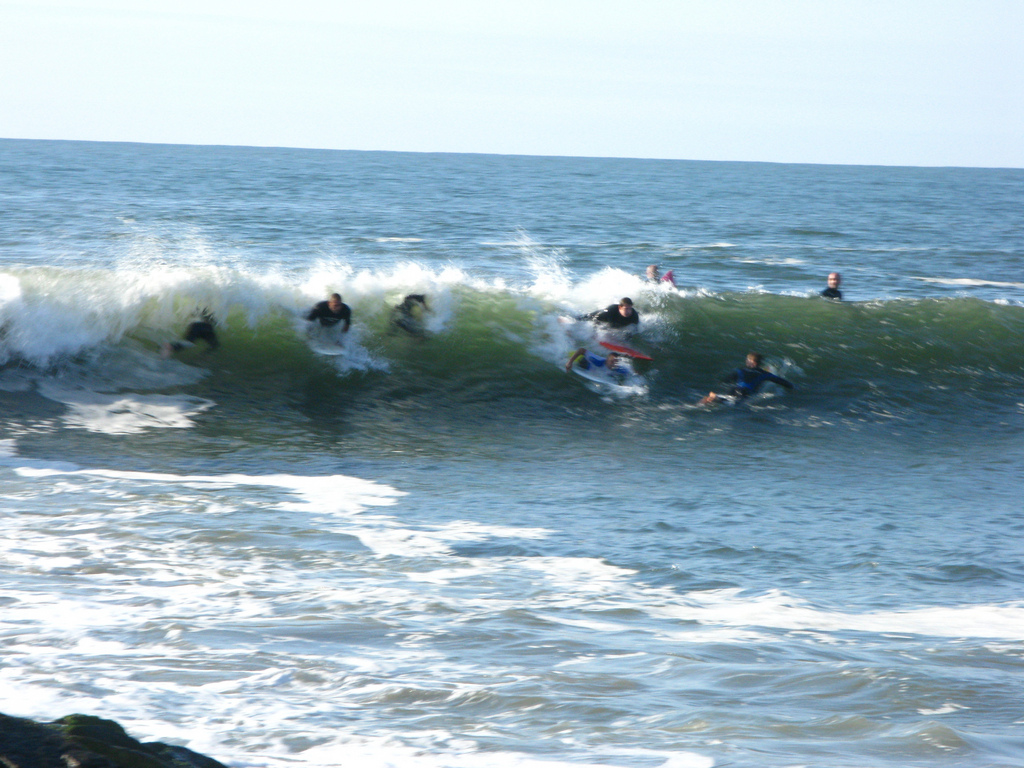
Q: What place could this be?
A: It is an ocean.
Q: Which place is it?
A: It is an ocean.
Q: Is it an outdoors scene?
A: Yes, it is outdoors.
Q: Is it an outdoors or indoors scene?
A: It is outdoors.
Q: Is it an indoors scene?
A: No, it is outdoors.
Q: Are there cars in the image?
A: No, there are no cars.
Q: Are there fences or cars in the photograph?
A: No, there are no cars or fences.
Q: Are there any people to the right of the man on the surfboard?
A: Yes, there are people to the right of the man.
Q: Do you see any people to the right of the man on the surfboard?
A: Yes, there are people to the right of the man.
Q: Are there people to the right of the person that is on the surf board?
A: Yes, there are people to the right of the man.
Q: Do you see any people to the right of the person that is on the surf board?
A: Yes, there are people to the right of the man.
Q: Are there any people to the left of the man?
A: No, the people are to the right of the man.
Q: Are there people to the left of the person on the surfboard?
A: No, the people are to the right of the man.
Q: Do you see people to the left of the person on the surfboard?
A: No, the people are to the right of the man.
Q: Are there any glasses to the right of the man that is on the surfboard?
A: No, there are people to the right of the man.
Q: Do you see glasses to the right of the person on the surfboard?
A: No, there are people to the right of the man.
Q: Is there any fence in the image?
A: No, there are no fences.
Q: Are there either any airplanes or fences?
A: No, there are no fences or airplanes.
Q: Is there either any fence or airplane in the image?
A: No, there are no fences or airplanes.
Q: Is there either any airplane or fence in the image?
A: No, there are no fences or airplanes.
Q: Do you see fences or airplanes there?
A: No, there are no fences or airplanes.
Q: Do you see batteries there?
A: No, there are no batteries.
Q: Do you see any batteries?
A: No, there are no batteries.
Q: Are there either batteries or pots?
A: No, there are no batteries or pots.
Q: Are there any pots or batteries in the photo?
A: No, there are no batteries or pots.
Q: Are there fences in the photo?
A: No, there are no fences.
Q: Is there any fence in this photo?
A: No, there are no fences.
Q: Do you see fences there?
A: No, there are no fences.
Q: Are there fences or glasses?
A: No, there are no fences or glasses.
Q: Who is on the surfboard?
A: The man is on the surfboard.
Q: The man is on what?
A: The man is on the surfboard.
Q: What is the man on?
A: The man is on the surfboard.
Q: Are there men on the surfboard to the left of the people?
A: Yes, there is a man on the surf board.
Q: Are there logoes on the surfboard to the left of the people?
A: No, there is a man on the surfboard.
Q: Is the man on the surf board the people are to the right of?
A: Yes, the man is on the surfboard.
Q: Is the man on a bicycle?
A: No, the man is on the surfboard.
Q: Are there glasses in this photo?
A: No, there are no glasses.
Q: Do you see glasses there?
A: No, there are no glasses.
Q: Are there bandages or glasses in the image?
A: No, there are no glasses or bandages.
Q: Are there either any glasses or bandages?
A: No, there are no glasses or bandages.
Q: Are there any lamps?
A: No, there are no lamps.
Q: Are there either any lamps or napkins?
A: No, there are no lamps or napkins.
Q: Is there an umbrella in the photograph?
A: No, there are no umbrellas.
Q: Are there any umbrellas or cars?
A: No, there are no umbrellas or cars.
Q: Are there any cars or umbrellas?
A: No, there are no umbrellas or cars.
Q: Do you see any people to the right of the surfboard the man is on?
A: Yes, there are people to the right of the surfboard.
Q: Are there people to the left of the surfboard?
A: No, the people are to the right of the surfboard.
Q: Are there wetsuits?
A: Yes, there is a wetsuit.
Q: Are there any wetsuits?
A: Yes, there is a wetsuit.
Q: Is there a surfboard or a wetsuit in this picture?
A: Yes, there is a wetsuit.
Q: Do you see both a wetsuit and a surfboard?
A: Yes, there are both a wetsuit and a surfboard.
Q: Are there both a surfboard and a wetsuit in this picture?
A: Yes, there are both a wetsuit and a surfboard.